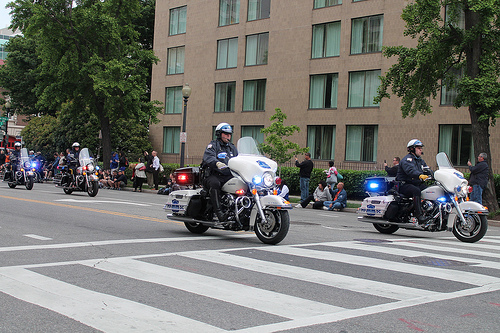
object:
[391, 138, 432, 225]
cops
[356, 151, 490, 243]
bikes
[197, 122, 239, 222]
cop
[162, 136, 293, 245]
bike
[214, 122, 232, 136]
helmet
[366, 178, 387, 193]
light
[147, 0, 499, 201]
building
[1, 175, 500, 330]
street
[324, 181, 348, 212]
people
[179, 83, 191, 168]
lamp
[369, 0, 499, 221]
trees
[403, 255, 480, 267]
hole